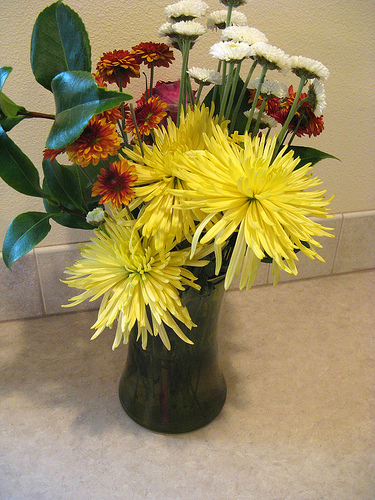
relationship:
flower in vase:
[132, 39, 176, 71] [118, 277, 228, 432]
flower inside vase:
[59, 204, 226, 351] [112, 275, 239, 434]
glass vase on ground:
[119, 273, 228, 433] [3, 269, 371, 498]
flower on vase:
[208, 39, 252, 64] [118, 277, 228, 432]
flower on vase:
[285, 55, 331, 80] [118, 277, 228, 432]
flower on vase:
[306, 77, 325, 114] [118, 277, 228, 432]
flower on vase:
[186, 66, 225, 86] [118, 277, 228, 432]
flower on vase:
[171, 21, 204, 36] [118, 277, 228, 432]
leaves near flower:
[53, 80, 101, 122] [58, 102, 334, 341]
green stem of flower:
[173, 41, 197, 114] [172, 20, 207, 41]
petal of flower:
[242, 213, 253, 248] [177, 130, 337, 286]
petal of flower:
[253, 198, 271, 226] [177, 130, 337, 286]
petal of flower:
[257, 223, 272, 258] [177, 130, 337, 286]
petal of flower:
[200, 197, 238, 212] [177, 130, 337, 286]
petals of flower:
[50, 210, 200, 349] [66, 115, 125, 166]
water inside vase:
[118, 340, 227, 432] [118, 277, 228, 432]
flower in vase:
[205, 56, 256, 114] [101, 94, 261, 439]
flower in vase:
[94, 163, 140, 211] [143, 306, 219, 425]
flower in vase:
[183, 66, 224, 91] [103, 210, 238, 432]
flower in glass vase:
[164, 17, 207, 126] [119, 273, 228, 433]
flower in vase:
[205, 7, 246, 31] [118, 277, 228, 432]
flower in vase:
[153, 76, 189, 112] [112, 203, 236, 434]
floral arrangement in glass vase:
[0, 2, 346, 350] [117, 230, 229, 434]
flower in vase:
[209, 40, 257, 63] [98, 265, 245, 443]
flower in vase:
[110, 91, 167, 139] [114, 255, 232, 427]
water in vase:
[118, 345, 227, 432] [118, 277, 228, 432]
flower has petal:
[186, 66, 225, 86] [184, 65, 199, 79]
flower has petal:
[289, 53, 328, 80] [309, 57, 315, 71]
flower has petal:
[207, 40, 253, 63] [233, 44, 239, 61]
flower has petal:
[171, 19, 205, 35] [186, 24, 189, 34]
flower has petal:
[164, 0, 209, 20] [179, 1, 185, 15]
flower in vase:
[109, 224, 239, 436] [84, 219, 270, 451]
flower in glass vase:
[96, 49, 143, 89] [119, 273, 228, 433]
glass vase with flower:
[119, 273, 228, 433] [96, 49, 143, 89]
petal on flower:
[139, 273, 158, 299] [71, 213, 180, 313]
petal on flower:
[148, 268, 174, 288] [71, 213, 180, 313]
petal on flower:
[116, 282, 122, 305] [71, 213, 180, 313]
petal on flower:
[91, 264, 125, 276] [71, 213, 180, 313]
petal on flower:
[158, 262, 183, 279] [71, 213, 180, 313]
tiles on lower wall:
[4, 210, 373, 324] [0, 209, 372, 316]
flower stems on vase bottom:
[129, 294, 215, 402] [113, 371, 236, 429]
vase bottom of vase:
[113, 371, 236, 429] [114, 255, 232, 427]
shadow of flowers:
[3, 289, 252, 446] [74, 26, 262, 223]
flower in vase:
[119, 101, 240, 251] [116, 263, 225, 424]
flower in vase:
[174, 122, 333, 290] [117, 255, 238, 433]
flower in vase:
[186, 66, 225, 86] [118, 277, 228, 432]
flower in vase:
[209, 41, 257, 63] [118, 277, 228, 432]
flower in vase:
[285, 55, 331, 80] [118, 277, 228, 432]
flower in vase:
[246, 77, 289, 99] [118, 277, 228, 432]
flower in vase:
[165, 0, 210, 18] [118, 277, 228, 432]